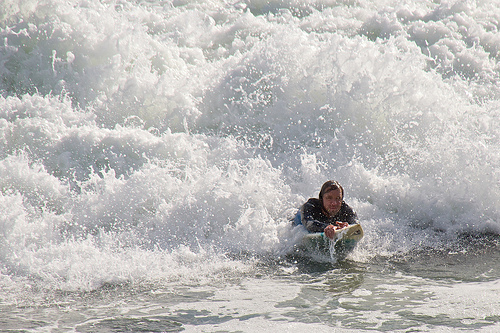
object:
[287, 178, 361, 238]
man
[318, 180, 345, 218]
head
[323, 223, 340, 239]
hand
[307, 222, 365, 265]
surfboard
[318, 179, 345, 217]
hair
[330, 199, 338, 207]
nose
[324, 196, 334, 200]
eye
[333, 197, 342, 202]
eye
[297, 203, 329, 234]
arm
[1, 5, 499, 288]
wave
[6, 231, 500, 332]
water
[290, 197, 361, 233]
wetsuit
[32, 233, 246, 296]
splashes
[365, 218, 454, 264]
splashes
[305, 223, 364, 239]
edge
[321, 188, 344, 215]
face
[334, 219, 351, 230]
hand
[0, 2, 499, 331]
picture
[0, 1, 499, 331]
daytime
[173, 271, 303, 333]
sud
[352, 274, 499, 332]
sud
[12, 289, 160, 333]
sud